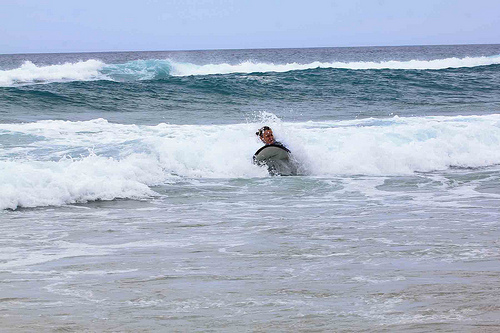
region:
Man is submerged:
[240, 113, 322, 191]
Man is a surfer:
[232, 101, 329, 206]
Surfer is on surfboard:
[218, 114, 315, 190]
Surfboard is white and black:
[246, 135, 304, 182]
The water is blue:
[9, 54, 496, 316]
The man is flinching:
[227, 109, 308, 180]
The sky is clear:
[2, 0, 497, 61]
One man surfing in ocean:
[207, 95, 338, 178]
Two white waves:
[10, 40, 496, 200]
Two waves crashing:
[2, 55, 498, 212]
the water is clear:
[339, 228, 356, 258]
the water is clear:
[346, 265, 358, 302]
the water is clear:
[370, 250, 385, 302]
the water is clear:
[339, 278, 349, 300]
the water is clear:
[337, 281, 357, 318]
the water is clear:
[319, 283, 335, 311]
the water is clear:
[322, 283, 342, 316]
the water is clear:
[297, 305, 314, 320]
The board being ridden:
[252, 141, 288, 165]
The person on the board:
[251, 120, 288, 147]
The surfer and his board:
[246, 118, 294, 173]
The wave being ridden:
[4, 106, 499, 213]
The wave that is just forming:
[0, 56, 499, 88]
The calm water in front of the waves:
[1, 208, 499, 331]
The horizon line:
[1, 39, 498, 54]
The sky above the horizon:
[0, 0, 497, 57]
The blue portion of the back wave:
[103, 56, 170, 86]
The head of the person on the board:
[254, 121, 275, 142]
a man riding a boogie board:
[247, 125, 294, 177]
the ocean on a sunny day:
[4, 40, 499, 207]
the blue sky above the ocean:
[0, 1, 495, 49]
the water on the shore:
[8, 212, 495, 332]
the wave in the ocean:
[10, 47, 499, 85]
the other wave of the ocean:
[13, 125, 485, 198]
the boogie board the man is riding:
[251, 145, 291, 180]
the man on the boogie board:
[253, 125, 275, 147]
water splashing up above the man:
[247, 100, 304, 157]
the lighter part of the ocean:
[362, 125, 426, 141]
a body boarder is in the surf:
[244, 113, 309, 179]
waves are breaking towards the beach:
[2, 113, 499, 288]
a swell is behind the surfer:
[16, 65, 499, 105]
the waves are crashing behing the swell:
[8, 55, 499, 74]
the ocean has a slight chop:
[3, 38, 499, 60]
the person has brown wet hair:
[251, 122, 276, 145]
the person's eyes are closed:
[254, 122, 279, 149]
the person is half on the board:
[246, 125, 305, 179]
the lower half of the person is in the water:
[248, 125, 310, 181]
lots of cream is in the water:
[3, 109, 497, 201]